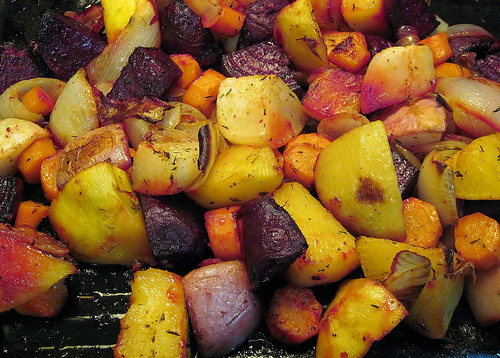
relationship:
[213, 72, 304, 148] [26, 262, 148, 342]
potato on grill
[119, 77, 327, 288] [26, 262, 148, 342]
vegetables on grill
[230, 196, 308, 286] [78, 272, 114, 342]
potato on grill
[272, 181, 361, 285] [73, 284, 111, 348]
potato on grill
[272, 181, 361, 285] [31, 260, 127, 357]
potato in grill